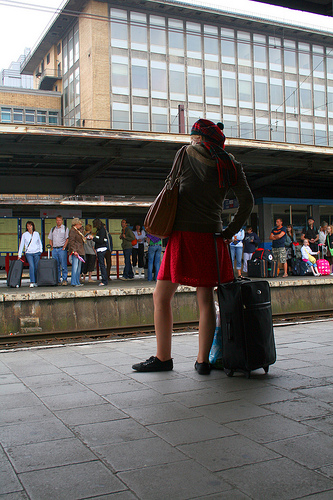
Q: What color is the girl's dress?
A: Red.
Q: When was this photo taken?
A: Daytime.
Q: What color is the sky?
A: White.